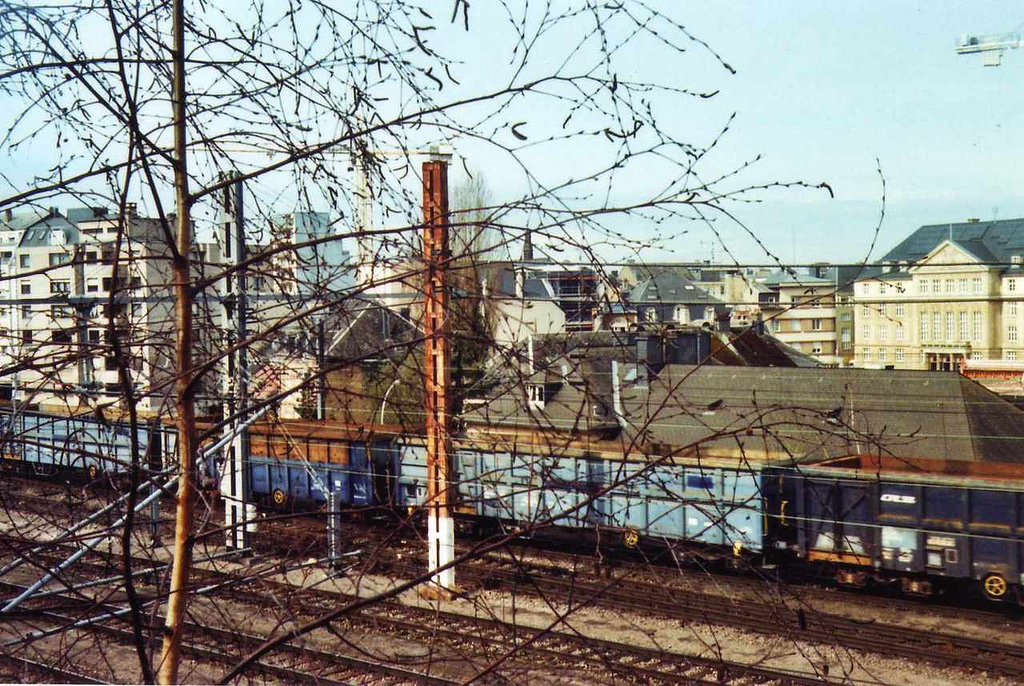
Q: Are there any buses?
A: No, there are no buses.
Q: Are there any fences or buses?
A: No, there are no buses or fences.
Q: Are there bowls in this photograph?
A: No, there are no bowls.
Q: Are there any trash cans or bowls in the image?
A: No, there are no bowls or trash cans.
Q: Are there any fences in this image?
A: No, there are no fences.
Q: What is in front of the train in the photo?
A: The tree is in front of the train.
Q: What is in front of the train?
A: The tree is in front of the train.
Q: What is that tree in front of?
A: The tree is in front of the train.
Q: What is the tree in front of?
A: The tree is in front of the train.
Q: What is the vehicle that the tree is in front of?
A: The vehicle is a train.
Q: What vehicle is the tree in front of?
A: The tree is in front of the train.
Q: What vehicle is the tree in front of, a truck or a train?
A: The tree is in front of a train.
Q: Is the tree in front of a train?
A: Yes, the tree is in front of a train.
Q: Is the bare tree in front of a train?
A: Yes, the tree is in front of a train.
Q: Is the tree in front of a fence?
A: No, the tree is in front of a train.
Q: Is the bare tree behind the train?
A: No, the tree is in front of the train.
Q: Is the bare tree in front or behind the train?
A: The tree is in front of the train.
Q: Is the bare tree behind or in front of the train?
A: The tree is in front of the train.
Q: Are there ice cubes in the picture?
A: No, there are no ice cubes.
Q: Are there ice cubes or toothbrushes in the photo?
A: No, there are no ice cubes or toothbrushes.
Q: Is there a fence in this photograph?
A: No, there are no fences.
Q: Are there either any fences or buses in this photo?
A: No, there are no fences or buses.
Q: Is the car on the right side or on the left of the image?
A: The car is on the right of the image.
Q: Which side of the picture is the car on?
A: The car is on the right of the image.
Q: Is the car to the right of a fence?
A: No, the car is to the right of the train car.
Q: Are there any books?
A: No, there are no books.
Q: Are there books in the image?
A: No, there are no books.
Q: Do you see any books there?
A: No, there are no books.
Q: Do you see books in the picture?
A: No, there are no books.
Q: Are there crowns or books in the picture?
A: No, there are no books or crowns.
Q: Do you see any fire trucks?
A: No, there are no fire trucks.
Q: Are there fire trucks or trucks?
A: No, there are no fire trucks or trucks.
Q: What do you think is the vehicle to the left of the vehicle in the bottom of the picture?
A: The vehicle is a train car.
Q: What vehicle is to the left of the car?
A: The vehicle is a train car.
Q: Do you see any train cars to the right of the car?
A: No, the train car is to the left of the car.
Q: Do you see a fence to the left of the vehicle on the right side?
A: No, there is a train car to the left of the car.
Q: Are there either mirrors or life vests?
A: No, there are no mirrors or life vests.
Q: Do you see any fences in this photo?
A: No, there are no fences.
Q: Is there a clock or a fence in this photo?
A: No, there are no fences or clocks.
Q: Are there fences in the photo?
A: No, there are no fences.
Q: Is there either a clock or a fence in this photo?
A: No, there are no fences or clocks.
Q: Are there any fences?
A: No, there are no fences.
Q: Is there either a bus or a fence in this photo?
A: No, there are no fences or buses.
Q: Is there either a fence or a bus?
A: No, there are no fences or buses.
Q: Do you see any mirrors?
A: No, there are no mirrors.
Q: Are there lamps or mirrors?
A: No, there are no mirrors or lamps.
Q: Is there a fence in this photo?
A: No, there are no fences.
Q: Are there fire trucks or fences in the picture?
A: No, there are no fences or fire trucks.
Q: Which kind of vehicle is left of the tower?
A: The vehicle is a train car.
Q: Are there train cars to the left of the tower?
A: Yes, there is a train car to the left of the tower.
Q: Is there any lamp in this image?
A: No, there are no lamps.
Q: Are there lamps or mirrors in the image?
A: No, there are no lamps or mirrors.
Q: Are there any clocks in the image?
A: No, there are no clocks.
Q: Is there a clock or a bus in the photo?
A: No, there are no clocks or buses.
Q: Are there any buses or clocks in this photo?
A: No, there are no clocks or buses.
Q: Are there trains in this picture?
A: Yes, there is a train.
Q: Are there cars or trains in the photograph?
A: Yes, there is a train.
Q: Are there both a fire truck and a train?
A: No, there is a train but no fire trucks.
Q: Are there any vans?
A: No, there are no vans.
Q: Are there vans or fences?
A: No, there are no vans or fences.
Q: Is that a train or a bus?
A: That is a train.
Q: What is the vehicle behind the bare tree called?
A: The vehicle is a train.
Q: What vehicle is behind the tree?
A: The vehicle is a train.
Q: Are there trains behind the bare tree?
A: Yes, there is a train behind the tree.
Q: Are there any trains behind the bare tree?
A: Yes, there is a train behind the tree.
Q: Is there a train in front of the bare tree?
A: No, the train is behind the tree.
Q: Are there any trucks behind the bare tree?
A: No, there is a train behind the tree.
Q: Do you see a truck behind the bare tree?
A: No, there is a train behind the tree.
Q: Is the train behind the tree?
A: Yes, the train is behind the tree.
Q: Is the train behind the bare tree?
A: Yes, the train is behind the tree.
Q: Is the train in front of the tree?
A: No, the train is behind the tree.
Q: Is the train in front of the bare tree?
A: No, the train is behind the tree.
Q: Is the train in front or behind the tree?
A: The train is behind the tree.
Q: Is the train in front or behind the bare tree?
A: The train is behind the tree.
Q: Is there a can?
A: No, there are no cans.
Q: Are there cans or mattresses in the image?
A: No, there are no cans or mattresses.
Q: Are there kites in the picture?
A: No, there are no kites.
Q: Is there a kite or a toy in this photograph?
A: No, there are no kites or toys.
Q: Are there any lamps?
A: No, there are no lamps.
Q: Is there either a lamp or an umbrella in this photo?
A: No, there are no lamps or umbrellas.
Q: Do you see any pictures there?
A: No, there are no pictures.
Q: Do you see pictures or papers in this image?
A: No, there are no pictures or papers.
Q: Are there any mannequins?
A: No, there are no mannequins.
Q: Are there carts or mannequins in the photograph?
A: No, there are no mannequins or carts.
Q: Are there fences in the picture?
A: No, there are no fences.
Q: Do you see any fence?
A: No, there are no fences.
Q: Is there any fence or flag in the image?
A: No, there are no fences or flags.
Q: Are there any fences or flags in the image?
A: No, there are no fences or flags.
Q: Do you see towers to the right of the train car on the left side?
A: Yes, there is a tower to the right of the train car.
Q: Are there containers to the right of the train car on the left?
A: No, there is a tower to the right of the train car.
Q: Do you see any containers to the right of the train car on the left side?
A: No, there is a tower to the right of the train car.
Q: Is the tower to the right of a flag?
A: No, the tower is to the right of a train car.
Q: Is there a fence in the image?
A: No, there are no fences.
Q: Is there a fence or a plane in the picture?
A: No, there are no fences or airplanes.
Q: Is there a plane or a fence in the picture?
A: No, there are no fences or airplanes.